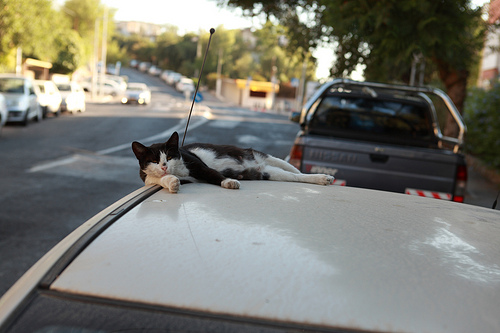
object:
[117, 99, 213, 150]
line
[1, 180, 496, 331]
car roof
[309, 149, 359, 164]
nissan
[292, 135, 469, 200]
back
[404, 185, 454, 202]
stripes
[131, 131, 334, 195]
cat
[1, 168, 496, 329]
hood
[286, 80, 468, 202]
car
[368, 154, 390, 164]
handle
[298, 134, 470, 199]
truck back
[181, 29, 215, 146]
antenna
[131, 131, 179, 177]
head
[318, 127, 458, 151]
bed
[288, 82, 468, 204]
pickup truck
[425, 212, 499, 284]
reflection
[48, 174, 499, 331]
roof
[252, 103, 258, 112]
cones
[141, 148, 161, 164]
black spot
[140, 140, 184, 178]
cat's face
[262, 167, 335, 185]
cat leg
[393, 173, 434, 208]
ground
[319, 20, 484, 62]
leaves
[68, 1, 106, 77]
trees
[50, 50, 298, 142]
road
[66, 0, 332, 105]
hill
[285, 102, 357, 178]
wall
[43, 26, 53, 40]
leaves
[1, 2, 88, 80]
tree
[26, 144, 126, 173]
line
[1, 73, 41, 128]
cars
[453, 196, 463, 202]
brake light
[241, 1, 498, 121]
trees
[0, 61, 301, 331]
street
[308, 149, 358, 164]
word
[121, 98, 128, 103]
headlights